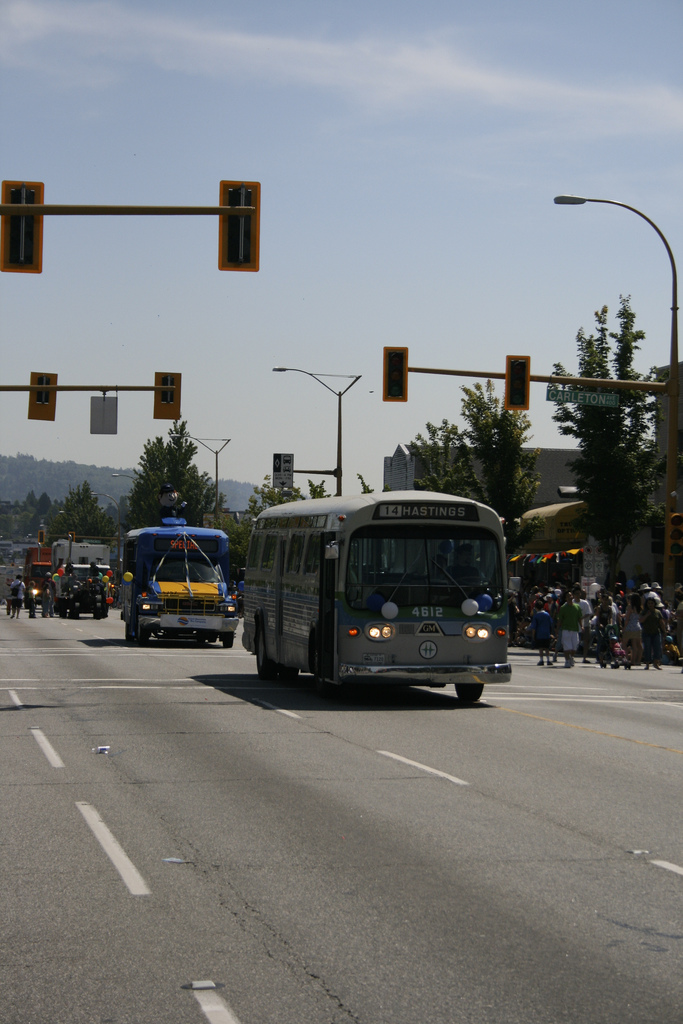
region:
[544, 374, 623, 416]
green street sign hanging from pole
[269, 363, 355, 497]
street light with black and white sign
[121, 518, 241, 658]
blue bus with orange hood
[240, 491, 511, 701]
white and green bus with yellow headlights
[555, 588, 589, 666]
man in green shirt and white shorts walking down street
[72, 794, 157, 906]
white stripe painted on road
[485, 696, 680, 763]
yellow line painted on road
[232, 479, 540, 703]
white bus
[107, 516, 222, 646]
blue bus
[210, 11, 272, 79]
white clouds in the blue sky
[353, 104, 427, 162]
white clouds in the blue sky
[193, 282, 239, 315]
white clouds in the blue sky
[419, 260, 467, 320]
white clouds in the blue sky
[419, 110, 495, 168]
white clouds in the blue sky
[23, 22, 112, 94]
white clouds in the blue sky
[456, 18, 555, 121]
white clouds in the blue sky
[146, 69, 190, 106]
white clouds in the blue sky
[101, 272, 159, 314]
white clouds in the blue sky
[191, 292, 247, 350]
white clouds in the blue sky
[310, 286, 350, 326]
white clouds in the blue sky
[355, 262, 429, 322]
white clouds in the blue sky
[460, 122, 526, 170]
white clouds in the blue sky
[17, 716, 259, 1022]
White lines located on the roadway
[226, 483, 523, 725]
A large city bus going down the road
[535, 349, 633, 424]
A street sign that says Carelton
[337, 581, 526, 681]
Blue and white balloons on the front of the bus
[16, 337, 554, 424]
A group of street lights above the road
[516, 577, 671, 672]
A large group of people watching a parade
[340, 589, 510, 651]
Working head lights located on the bus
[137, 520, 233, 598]
Streamer on the front of the truck for the parade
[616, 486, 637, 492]
green leaves on the tree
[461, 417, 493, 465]
green leaves on the tree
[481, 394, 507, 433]
green leaves on the tree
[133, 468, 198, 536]
green leaves on the tree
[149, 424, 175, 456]
green leaves on the tree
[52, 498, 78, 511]
green leaves on the tree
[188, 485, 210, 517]
green leaves on the tree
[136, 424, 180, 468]
green leaves on the tree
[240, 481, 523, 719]
silver metal bus on road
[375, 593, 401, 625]
white ballon on bus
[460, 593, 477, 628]
white ballon on bus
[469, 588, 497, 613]
blue ballon on bus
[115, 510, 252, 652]
blue and yellow van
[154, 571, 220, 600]
yellow front of van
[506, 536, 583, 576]
colorful hanging row of flags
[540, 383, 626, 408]
green and white street sign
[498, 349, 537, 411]
yellow plastic frame of traffic light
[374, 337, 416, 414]
yellow plastic frame of traffic light